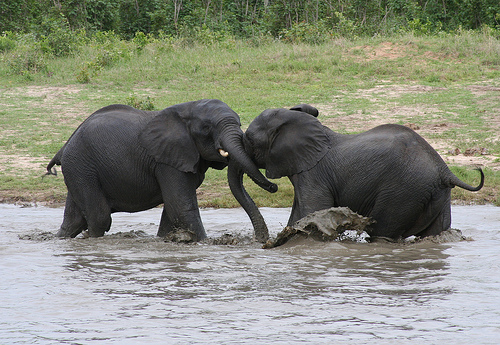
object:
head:
[136, 97, 279, 194]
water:
[0, 298, 117, 344]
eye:
[201, 124, 209, 130]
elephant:
[43, 98, 280, 243]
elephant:
[226, 104, 485, 245]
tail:
[46, 157, 57, 176]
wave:
[336, 281, 451, 295]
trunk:
[226, 151, 269, 243]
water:
[402, 276, 499, 344]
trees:
[124, 1, 280, 58]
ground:
[421, 73, 484, 144]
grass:
[286, 67, 355, 97]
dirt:
[373, 71, 425, 93]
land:
[450, 31, 485, 138]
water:
[188, 249, 341, 287]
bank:
[0, 182, 67, 215]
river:
[7, 249, 243, 335]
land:
[14, 17, 486, 113]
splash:
[283, 206, 377, 242]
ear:
[264, 109, 331, 179]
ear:
[289, 103, 321, 118]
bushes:
[0, 0, 495, 35]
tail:
[450, 167, 485, 192]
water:
[393, 227, 461, 275]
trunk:
[221, 126, 279, 194]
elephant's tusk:
[218, 148, 228, 157]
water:
[163, 282, 320, 343]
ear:
[136, 106, 199, 175]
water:
[0, 210, 47, 255]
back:
[101, 109, 152, 136]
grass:
[0, 31, 240, 48]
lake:
[0, 189, 497, 345]